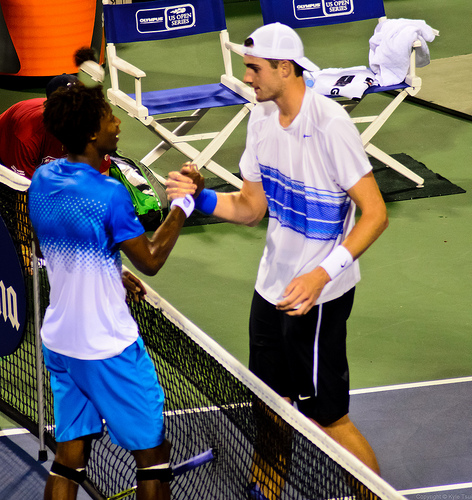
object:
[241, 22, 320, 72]
cap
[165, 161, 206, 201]
holding hands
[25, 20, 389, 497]
two men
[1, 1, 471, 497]
court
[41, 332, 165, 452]
blue shorts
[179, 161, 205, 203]
hand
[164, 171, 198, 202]
hand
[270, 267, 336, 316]
hand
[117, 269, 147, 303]
hand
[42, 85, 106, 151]
black hair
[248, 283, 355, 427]
shorts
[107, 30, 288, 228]
chair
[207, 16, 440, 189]
chair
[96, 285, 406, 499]
net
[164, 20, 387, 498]
man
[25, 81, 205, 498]
man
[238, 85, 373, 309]
shirt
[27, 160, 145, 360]
shirt